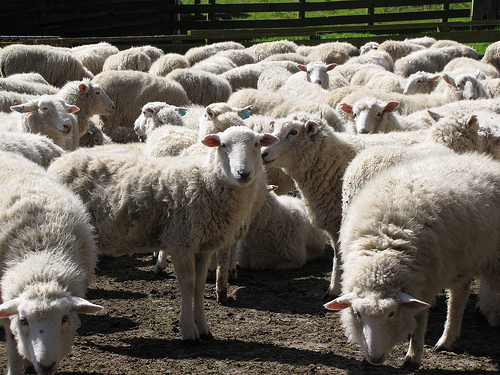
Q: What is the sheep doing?
A: Moving.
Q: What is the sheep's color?
A: White.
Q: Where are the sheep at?
A: Pen.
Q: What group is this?
A: Sheep.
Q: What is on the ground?
A: A sheep.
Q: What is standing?
A: Sheep.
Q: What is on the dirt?
A: Few patches of grass.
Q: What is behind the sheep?
A: A fence.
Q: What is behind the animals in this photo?
A: A few fence rails.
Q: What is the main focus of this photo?
A: A herd of sheep.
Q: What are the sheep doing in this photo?
A: Herding together.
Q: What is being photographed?
A: A flock of sheep in their pen.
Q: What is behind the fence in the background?
A: Green grass behind a fence.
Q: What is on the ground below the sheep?
A: A shadow is cast on the ground.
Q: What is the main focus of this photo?
A: Lots of sheep.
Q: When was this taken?
A: During the day.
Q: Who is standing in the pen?
A: Sheep.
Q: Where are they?
A: On the dirt.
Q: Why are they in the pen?
A: To stay safe.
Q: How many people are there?
A: 0.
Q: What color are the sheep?
A: White.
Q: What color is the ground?
A: Brown.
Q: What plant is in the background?
A: Grass.